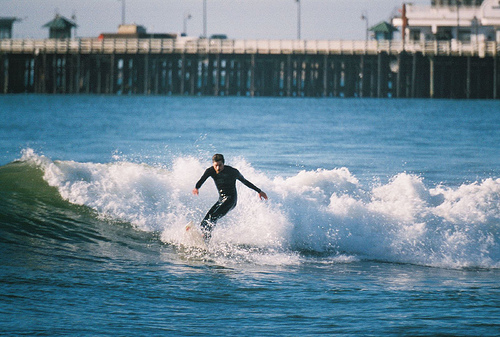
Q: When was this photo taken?
A: During the day.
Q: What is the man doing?
A: Surfing.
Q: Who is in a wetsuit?
A: A surfer.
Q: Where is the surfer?
A: On the water.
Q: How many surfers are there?
A: One.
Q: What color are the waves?
A: White.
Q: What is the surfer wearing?
A: A wet suit.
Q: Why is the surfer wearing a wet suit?
A: Because he's in the water.